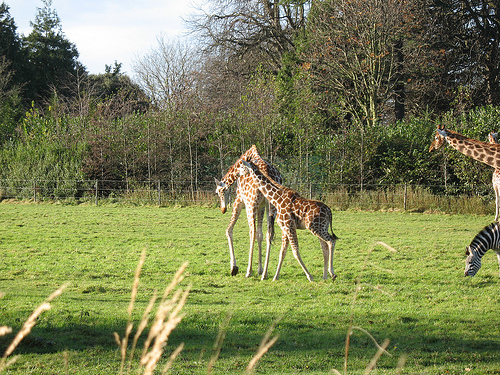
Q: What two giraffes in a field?
A: Two on the green grass.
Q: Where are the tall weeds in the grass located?
A: Left.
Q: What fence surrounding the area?
A: Where the animals are.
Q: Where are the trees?
A: Behind the fence.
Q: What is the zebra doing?
A: Eating.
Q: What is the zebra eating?
A: Grass.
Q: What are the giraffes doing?
A: Playing.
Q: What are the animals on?
A: Grass.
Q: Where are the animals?
A: A field.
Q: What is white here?
A: Clouds.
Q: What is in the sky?
A: Clouds.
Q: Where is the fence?
A: By the trees.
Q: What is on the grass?
A: Animals.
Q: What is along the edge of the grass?
A: Fencing.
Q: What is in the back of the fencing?
A: Trees.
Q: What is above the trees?
A: Blue sky with clouds.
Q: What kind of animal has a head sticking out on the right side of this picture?
A: A zebra and a giraffe.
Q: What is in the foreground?
A: Heads of golden grasses pointing upwards.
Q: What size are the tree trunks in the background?
A: Slender trunks.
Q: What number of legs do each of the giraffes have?
A: Four legs.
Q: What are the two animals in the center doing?
A: Walking.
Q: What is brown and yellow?
A: A giraffe.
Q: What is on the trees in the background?
A: Leaves.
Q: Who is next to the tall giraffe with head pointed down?
A: Small giraffe.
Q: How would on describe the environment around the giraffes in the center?
A: Flat and grassy.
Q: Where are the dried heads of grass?
A: Foreground of photo.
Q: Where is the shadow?
A: Foreground of the scene.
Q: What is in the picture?
A: Giraffes.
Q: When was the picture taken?
A: In the daytime.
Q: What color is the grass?
A: Green.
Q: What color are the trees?
A: Dark green.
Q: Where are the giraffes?
A: In the field.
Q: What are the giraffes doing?
A: Walking around.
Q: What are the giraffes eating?
A: Grass.